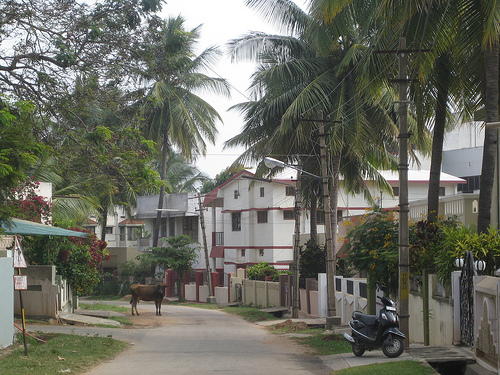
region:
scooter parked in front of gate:
[343, 292, 408, 362]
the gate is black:
[455, 250, 480, 348]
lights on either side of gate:
[452, 249, 489, 276]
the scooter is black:
[347, 294, 406, 362]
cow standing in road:
[81, 277, 326, 374]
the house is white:
[211, 164, 468, 294]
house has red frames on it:
[216, 199, 398, 274]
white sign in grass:
[13, 234, 33, 359]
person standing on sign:
[14, 242, 25, 265]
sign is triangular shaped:
[11, 234, 26, 270]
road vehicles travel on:
[170, 310, 255, 371]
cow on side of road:
[119, 274, 172, 313]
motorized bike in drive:
[341, 282, 403, 364]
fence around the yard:
[236, 275, 279, 305]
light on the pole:
[261, 150, 289, 175]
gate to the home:
[454, 241, 479, 348]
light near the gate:
[470, 256, 488, 273]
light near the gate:
[451, 245, 466, 272]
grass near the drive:
[363, 365, 425, 373]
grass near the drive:
[316, 338, 347, 355]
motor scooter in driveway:
[342, 297, 417, 370]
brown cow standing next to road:
[114, 269, 191, 318]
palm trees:
[141, 15, 405, 182]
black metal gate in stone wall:
[442, 244, 489, 353]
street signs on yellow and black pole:
[3, 233, 46, 359]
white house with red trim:
[207, 161, 302, 268]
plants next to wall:
[304, 214, 499, 296]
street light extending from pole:
[259, 149, 336, 228]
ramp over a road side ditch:
[408, 339, 487, 373]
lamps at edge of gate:
[444, 244, 499, 279]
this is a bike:
[325, 294, 420, 364]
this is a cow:
[116, 275, 181, 327]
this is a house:
[211, 134, 461, 349]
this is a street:
[12, 277, 341, 374]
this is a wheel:
[376, 334, 408, 361]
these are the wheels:
[347, 330, 410, 362]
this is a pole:
[286, 90, 364, 367]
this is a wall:
[210, 260, 498, 355]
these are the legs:
[124, 298, 169, 323]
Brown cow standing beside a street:
[127, 280, 168, 315]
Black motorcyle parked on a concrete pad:
[348, 297, 407, 361]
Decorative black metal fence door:
[456, 246, 475, 352]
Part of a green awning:
[2, 212, 89, 242]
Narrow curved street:
[83, 299, 326, 374]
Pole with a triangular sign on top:
[11, 232, 31, 356]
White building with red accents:
[202, 162, 464, 304]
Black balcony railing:
[210, 230, 225, 247]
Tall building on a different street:
[433, 108, 486, 193]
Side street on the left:
[14, 321, 142, 345]